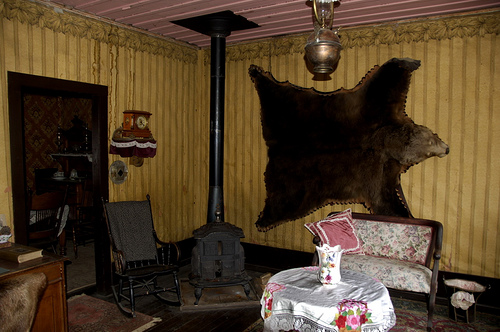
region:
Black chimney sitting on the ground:
[165, 10, 256, 301]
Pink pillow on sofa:
[301, 209, 366, 257]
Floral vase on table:
[313, 240, 347, 284]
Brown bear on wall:
[243, 55, 450, 235]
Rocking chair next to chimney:
[100, 191, 185, 317]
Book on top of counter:
[0, 240, 45, 263]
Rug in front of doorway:
[64, 292, 161, 330]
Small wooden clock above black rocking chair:
[119, 108, 156, 140]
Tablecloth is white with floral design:
[259, 263, 395, 330]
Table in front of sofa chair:
[261, 263, 401, 329]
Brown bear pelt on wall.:
[247, 63, 444, 237]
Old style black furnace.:
[177, 0, 269, 292]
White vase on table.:
[309, 236, 349, 291]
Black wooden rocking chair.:
[96, 189, 187, 326]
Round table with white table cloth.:
[265, 249, 395, 330]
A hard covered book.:
[0, 237, 56, 268]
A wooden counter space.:
[0, 215, 65, 328]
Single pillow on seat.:
[297, 198, 451, 312]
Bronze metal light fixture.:
[299, 0, 348, 90]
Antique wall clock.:
[113, 105, 165, 143]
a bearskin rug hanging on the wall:
[224, 61, 448, 212]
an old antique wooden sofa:
[317, 199, 448, 311]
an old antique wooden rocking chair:
[94, 183, 175, 305]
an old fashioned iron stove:
[185, 195, 247, 303]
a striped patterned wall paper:
[98, 31, 195, 99]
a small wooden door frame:
[12, 58, 127, 292]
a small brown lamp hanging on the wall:
[101, 102, 171, 187]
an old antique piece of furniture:
[437, 278, 492, 325]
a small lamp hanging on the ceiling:
[301, 16, 351, 100]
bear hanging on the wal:
[237, 53, 459, 243]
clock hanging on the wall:
[108, 105, 162, 171]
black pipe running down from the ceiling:
[188, 20, 235, 227]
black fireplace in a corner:
[179, 213, 262, 296]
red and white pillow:
[300, 210, 370, 255]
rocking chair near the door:
[95, 190, 199, 321]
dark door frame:
[7, 69, 129, 295]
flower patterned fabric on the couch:
[321, 215, 439, 295]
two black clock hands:
[137, 117, 147, 127]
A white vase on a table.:
[306, 239, 349, 286]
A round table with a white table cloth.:
[263, 258, 396, 327]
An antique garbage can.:
[437, 263, 493, 322]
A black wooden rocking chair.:
[97, 191, 184, 311]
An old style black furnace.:
[183, 8, 261, 303]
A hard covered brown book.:
[2, 231, 48, 261]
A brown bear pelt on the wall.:
[234, 59, 439, 236]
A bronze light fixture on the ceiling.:
[297, 0, 358, 96]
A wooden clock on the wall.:
[109, 95, 164, 169]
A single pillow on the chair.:
[310, 207, 442, 287]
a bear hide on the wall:
[225, 44, 467, 271]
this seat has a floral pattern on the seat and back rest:
[290, 205, 492, 310]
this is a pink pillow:
[302, 201, 386, 267]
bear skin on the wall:
[220, 55, 440, 230]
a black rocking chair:
[85, 182, 190, 311]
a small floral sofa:
[309, 203, 462, 308]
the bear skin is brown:
[225, 52, 453, 236]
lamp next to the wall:
[108, 88, 175, 179]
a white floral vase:
[308, 235, 347, 290]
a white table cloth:
[255, 257, 390, 330]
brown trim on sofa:
[349, 206, 434, 233]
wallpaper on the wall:
[156, 41, 208, 235]